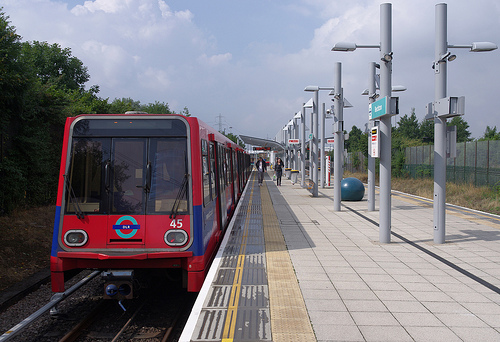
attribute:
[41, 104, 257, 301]
train — red, blue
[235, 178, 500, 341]
platform — concrete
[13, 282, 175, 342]
tracks — brown, metal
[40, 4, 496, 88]
clouds — fluffy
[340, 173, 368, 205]
ball — black, large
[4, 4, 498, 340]
day — sunny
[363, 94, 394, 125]
sign — green, white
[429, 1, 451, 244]
post — grey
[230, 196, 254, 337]
line — yellow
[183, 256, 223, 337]
line — white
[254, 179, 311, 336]
stripe — yellow, long